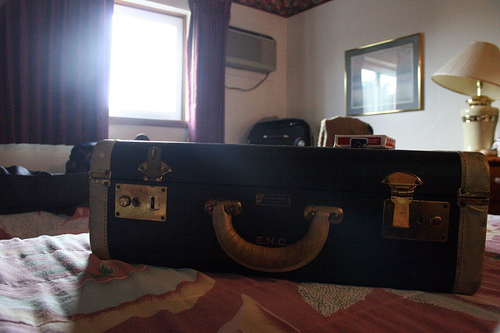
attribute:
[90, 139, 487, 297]
suitcase — old , leather 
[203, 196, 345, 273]
handle — bronze 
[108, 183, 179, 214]
lock — metal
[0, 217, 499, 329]
bedspread — multi-colored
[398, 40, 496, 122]
lampshade — White 